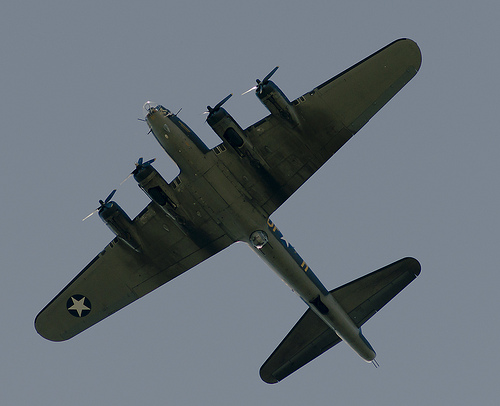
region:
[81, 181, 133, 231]
War plane propeller spinning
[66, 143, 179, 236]
Two war plane propellers spinning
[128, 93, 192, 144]
The nose section of an old war plane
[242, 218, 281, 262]
Belly gun turret of an old war plane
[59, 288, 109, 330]
Blue and white star on a planes wing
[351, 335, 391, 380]
Tail gun on a old war plane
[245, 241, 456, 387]
Tail section of a plane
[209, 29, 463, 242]
Left wing of an old war plane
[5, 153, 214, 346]
Right wing of an old war plane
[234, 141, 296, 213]
Fuel discoloration from engine under a planes wing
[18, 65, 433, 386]
Green plane is flying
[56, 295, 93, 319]
White star on wing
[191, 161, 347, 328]
Underside of plane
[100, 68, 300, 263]
Four engines have propellers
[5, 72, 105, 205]
Patch of blue sky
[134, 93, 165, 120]
Glass tip of plane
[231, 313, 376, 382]
Right tail fin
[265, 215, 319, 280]
Yellow lettering on side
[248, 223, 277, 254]
Glass circle on bottom of plane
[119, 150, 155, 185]
Propeller on tip of engine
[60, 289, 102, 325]
the star is blue and white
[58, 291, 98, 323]
the star is on the bottom of the planes wing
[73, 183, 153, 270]
the propeller is on the wing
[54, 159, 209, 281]
two propellers are on each wing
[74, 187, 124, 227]
each engine has 3 propeller blades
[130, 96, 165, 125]
the nose of the plane is clear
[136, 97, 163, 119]
the cockpit is in the nose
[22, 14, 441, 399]
the plane is a military plane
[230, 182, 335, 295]
the emblams are gold white and blue in color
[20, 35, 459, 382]
the basic color of the plane is green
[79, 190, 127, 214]
blue propeller on an airplane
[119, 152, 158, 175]
blue propeller on an airplane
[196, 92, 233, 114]
blue propeller on an airplane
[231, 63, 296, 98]
blue propeller on an airplane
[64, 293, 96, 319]
white star on the airplane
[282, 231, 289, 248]
white star on the tail of the plane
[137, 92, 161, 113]
glass tip of the plane nose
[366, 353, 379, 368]
metal prongs in the tail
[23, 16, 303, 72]
hazy blue sky overhead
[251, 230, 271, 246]
metal instrument under the plane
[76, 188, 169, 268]
engine on an airplane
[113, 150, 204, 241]
engine on an airplane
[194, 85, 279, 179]
engine on an airplane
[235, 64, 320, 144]
engine on an airplane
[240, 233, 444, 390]
tail on an airplane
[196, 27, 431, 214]
wing of an airplane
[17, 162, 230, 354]
wing of an airplane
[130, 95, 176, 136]
cockpit of an airplane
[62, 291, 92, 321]
logo on an airplane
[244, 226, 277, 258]
gunning turret on an airplane